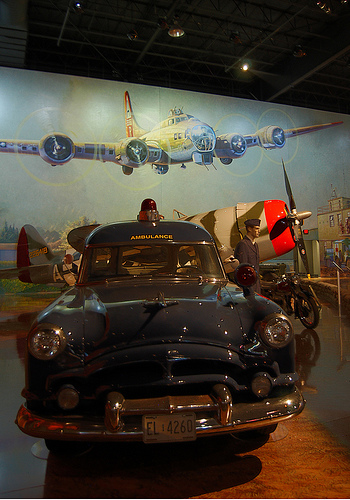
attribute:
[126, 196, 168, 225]
siren — silver, red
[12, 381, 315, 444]
bumper — silver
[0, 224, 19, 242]
tree — is painted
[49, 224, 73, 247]
tree — is painted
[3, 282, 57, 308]
grass — is painted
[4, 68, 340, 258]
wall — is painted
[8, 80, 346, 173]
plane — large, propeller plane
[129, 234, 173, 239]
text — yellow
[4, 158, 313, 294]
airplane — is vintage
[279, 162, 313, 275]
propeller — black, silver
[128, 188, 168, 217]
light — silver, Red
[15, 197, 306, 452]
ambulance — is blue, is old, blue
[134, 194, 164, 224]
light — is red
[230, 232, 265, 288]
uniform — sailor uniform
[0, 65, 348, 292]
painting — is vintage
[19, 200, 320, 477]
car — is antique